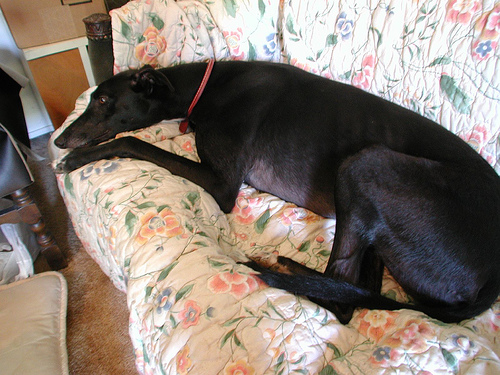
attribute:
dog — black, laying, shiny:
[53, 59, 500, 325]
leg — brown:
[12, 186, 68, 271]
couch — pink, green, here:
[48, 1, 500, 374]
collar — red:
[180, 60, 215, 136]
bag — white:
[0, 223, 42, 287]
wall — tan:
[1, 0, 106, 131]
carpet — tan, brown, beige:
[0, 134, 142, 374]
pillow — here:
[0, 271, 70, 374]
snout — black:
[55, 111, 115, 150]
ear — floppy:
[136, 65, 175, 98]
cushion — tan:
[0, 270, 70, 374]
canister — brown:
[83, 12, 116, 87]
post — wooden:
[84, 13, 117, 86]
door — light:
[0, 7, 56, 142]